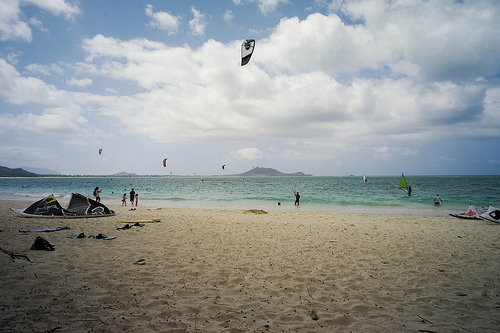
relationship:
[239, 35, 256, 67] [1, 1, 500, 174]
kite in sky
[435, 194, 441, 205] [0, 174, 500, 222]
person in water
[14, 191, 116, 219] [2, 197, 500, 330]
tent on beach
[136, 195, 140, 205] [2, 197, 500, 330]
child on beach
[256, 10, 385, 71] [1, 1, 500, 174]
cloud in sky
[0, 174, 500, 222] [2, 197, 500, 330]
water on beach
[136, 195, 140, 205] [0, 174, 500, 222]
child at water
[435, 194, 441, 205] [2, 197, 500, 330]
person on beach